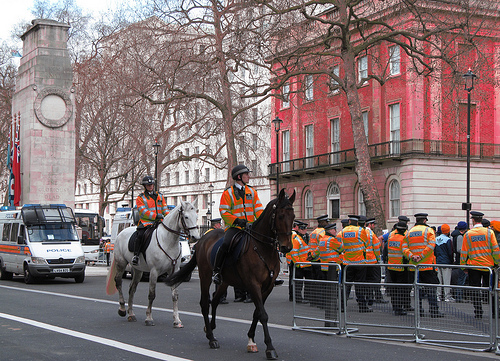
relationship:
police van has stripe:
[1, 203, 87, 283] [0, 244, 33, 256]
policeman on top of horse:
[212, 165, 265, 286] [166, 187, 295, 360]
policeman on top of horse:
[131, 176, 171, 266] [106, 196, 202, 329]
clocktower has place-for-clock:
[11, 19, 75, 215] [32, 84, 77, 128]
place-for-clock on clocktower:
[32, 84, 77, 128] [11, 19, 75, 215]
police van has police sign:
[1, 203, 87, 283] [45, 247, 71, 254]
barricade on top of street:
[291, 261, 500, 351] [1, 275, 500, 361]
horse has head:
[166, 187, 295, 360] [261, 187, 296, 254]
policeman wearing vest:
[212, 165, 265, 286] [218, 185, 263, 230]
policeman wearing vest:
[131, 176, 171, 266] [136, 191, 169, 227]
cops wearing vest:
[459, 211, 500, 319] [460, 228, 500, 273]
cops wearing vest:
[408, 213, 443, 318] [401, 225, 439, 271]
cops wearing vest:
[386, 222, 408, 316] [387, 234, 406, 272]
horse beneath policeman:
[166, 187, 295, 360] [212, 165, 265, 286]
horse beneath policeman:
[106, 196, 202, 329] [131, 176, 171, 266]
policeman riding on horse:
[212, 165, 265, 286] [166, 187, 295, 360]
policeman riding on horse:
[131, 176, 171, 266] [106, 196, 202, 329]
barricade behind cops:
[291, 261, 500, 351] [459, 211, 500, 319]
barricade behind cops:
[291, 261, 500, 351] [408, 213, 443, 318]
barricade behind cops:
[291, 261, 500, 351] [386, 222, 408, 316]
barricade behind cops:
[291, 261, 500, 351] [318, 223, 344, 328]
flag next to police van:
[14, 112, 21, 206] [1, 203, 87, 283]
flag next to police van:
[8, 115, 14, 207] [1, 203, 87, 283]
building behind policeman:
[270, 1, 500, 233] [212, 165, 265, 286]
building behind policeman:
[270, 1, 500, 233] [131, 176, 171, 266]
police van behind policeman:
[1, 203, 87, 283] [212, 165, 265, 286]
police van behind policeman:
[1, 203, 87, 283] [131, 176, 171, 266]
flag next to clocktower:
[14, 112, 21, 206] [11, 19, 75, 215]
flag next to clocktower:
[8, 115, 14, 207] [11, 19, 75, 215]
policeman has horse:
[212, 165, 265, 286] [166, 187, 295, 360]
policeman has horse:
[131, 176, 171, 266] [106, 196, 202, 329]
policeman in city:
[212, 165, 265, 286] [1, 0, 498, 361]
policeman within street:
[212, 165, 265, 286] [1, 275, 500, 361]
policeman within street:
[131, 176, 171, 266] [1, 275, 500, 361]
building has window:
[270, 1, 500, 233] [389, 45, 401, 77]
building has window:
[270, 1, 500, 233] [388, 101, 401, 158]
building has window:
[270, 1, 500, 233] [329, 118, 341, 165]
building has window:
[270, 1, 500, 233] [306, 124, 314, 169]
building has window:
[270, 1, 500, 233] [283, 128, 289, 170]